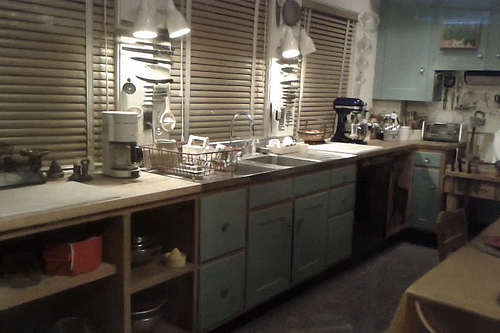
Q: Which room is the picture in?
A: It is at the kitchen.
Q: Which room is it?
A: It is a kitchen.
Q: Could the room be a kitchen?
A: Yes, it is a kitchen.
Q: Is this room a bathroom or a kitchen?
A: It is a kitchen.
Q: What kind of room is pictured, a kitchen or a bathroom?
A: It is a kitchen.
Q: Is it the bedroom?
A: No, it is the kitchen.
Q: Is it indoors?
A: Yes, it is indoors.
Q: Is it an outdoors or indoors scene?
A: It is indoors.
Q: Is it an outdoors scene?
A: No, it is indoors.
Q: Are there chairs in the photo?
A: Yes, there is a chair.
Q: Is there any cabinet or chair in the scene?
A: Yes, there is a chair.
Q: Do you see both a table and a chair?
A: Yes, there are both a chair and a table.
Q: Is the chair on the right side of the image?
A: Yes, the chair is on the right of the image.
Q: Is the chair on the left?
A: No, the chair is on the right of the image.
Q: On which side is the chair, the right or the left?
A: The chair is on the right of the image.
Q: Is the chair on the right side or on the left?
A: The chair is on the right of the image.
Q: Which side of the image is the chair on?
A: The chair is on the right of the image.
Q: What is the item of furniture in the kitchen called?
A: The piece of furniture is a chair.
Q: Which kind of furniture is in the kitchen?
A: The piece of furniture is a chair.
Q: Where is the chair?
A: The chair is in the kitchen.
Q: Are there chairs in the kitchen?
A: Yes, there is a chair in the kitchen.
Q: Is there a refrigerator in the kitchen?
A: No, there is a chair in the kitchen.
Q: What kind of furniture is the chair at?
A: The chair is at the table.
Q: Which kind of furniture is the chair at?
A: The chair is at the table.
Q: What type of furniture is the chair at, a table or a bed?
A: The chair is at a table.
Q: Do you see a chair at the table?
A: Yes, there is a chair at the table.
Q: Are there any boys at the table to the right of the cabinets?
A: No, there is a chair at the table.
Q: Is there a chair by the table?
A: Yes, there is a chair by the table.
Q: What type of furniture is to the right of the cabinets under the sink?
A: The piece of furniture is a chair.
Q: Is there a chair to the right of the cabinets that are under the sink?
A: Yes, there is a chair to the right of the cabinets.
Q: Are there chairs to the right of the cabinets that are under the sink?
A: Yes, there is a chair to the right of the cabinets.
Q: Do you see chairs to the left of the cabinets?
A: No, the chair is to the right of the cabinets.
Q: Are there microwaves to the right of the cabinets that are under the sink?
A: No, there is a chair to the right of the cabinets.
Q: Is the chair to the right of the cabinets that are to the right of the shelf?
A: Yes, the chair is to the right of the cabinets.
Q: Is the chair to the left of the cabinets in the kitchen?
A: No, the chair is to the right of the cabinets.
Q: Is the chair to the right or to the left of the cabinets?
A: The chair is to the right of the cabinets.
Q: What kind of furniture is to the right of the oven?
A: The piece of furniture is a chair.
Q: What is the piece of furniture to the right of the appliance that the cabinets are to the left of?
A: The piece of furniture is a chair.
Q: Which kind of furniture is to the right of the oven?
A: The piece of furniture is a chair.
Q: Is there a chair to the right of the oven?
A: Yes, there is a chair to the right of the oven.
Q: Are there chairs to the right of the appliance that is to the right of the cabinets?
A: Yes, there is a chair to the right of the oven.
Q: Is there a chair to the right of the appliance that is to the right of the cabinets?
A: Yes, there is a chair to the right of the oven.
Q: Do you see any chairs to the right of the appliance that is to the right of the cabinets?
A: Yes, there is a chair to the right of the oven.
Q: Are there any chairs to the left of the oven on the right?
A: No, the chair is to the right of the oven.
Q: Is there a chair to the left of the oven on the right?
A: No, the chair is to the right of the oven.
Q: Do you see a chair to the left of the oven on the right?
A: No, the chair is to the right of the oven.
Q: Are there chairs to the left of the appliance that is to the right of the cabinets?
A: No, the chair is to the right of the oven.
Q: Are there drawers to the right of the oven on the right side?
A: No, there is a chair to the right of the oven.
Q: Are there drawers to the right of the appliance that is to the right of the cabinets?
A: No, there is a chair to the right of the oven.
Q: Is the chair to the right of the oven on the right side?
A: Yes, the chair is to the right of the oven.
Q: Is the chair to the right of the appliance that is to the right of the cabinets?
A: Yes, the chair is to the right of the oven.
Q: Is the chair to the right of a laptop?
A: No, the chair is to the right of the oven.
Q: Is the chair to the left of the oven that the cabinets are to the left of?
A: No, the chair is to the right of the oven.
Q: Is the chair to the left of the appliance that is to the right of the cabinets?
A: No, the chair is to the right of the oven.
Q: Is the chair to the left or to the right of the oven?
A: The chair is to the right of the oven.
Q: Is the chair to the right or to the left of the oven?
A: The chair is to the right of the oven.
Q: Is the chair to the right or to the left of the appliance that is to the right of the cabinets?
A: The chair is to the right of the oven.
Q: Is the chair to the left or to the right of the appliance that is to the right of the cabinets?
A: The chair is to the right of the oven.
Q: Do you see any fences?
A: No, there are no fences.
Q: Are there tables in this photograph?
A: Yes, there is a table.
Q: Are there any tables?
A: Yes, there is a table.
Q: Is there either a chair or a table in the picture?
A: Yes, there is a table.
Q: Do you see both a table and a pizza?
A: No, there is a table but no pizzas.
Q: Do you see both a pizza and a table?
A: No, there is a table but no pizzas.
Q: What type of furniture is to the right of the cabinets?
A: The piece of furniture is a table.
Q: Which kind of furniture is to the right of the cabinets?
A: The piece of furniture is a table.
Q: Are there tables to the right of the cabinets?
A: Yes, there is a table to the right of the cabinets.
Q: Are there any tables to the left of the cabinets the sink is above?
A: No, the table is to the right of the cabinets.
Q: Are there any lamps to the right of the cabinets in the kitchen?
A: No, there is a table to the right of the cabinets.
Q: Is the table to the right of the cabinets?
A: Yes, the table is to the right of the cabinets.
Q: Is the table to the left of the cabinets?
A: No, the table is to the right of the cabinets.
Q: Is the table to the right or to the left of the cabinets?
A: The table is to the right of the cabinets.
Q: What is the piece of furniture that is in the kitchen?
A: The piece of furniture is a table.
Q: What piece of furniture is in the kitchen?
A: The piece of furniture is a table.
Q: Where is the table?
A: The table is in the kitchen.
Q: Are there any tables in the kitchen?
A: Yes, there is a table in the kitchen.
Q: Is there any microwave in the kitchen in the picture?
A: No, there is a table in the kitchen.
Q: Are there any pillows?
A: No, there are no pillows.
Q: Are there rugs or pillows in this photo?
A: No, there are no pillows or rugs.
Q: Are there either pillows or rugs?
A: No, there are no pillows or rugs.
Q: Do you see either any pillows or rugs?
A: No, there are no pillows or rugs.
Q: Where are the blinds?
A: The blinds are in the kitchen.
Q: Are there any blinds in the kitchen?
A: Yes, there are blinds in the kitchen.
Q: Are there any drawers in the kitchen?
A: No, there are blinds in the kitchen.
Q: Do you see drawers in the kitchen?
A: No, there are blinds in the kitchen.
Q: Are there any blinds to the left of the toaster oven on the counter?
A: Yes, there are blinds to the left of the toaster oven.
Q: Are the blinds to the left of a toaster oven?
A: Yes, the blinds are to the left of a toaster oven.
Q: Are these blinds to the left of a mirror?
A: No, the blinds are to the left of a toaster oven.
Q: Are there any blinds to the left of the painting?
A: Yes, there are blinds to the left of the painting.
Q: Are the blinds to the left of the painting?
A: Yes, the blinds are to the left of the painting.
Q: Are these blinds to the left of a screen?
A: No, the blinds are to the left of the painting.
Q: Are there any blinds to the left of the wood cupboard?
A: Yes, there are blinds to the left of the cupboard.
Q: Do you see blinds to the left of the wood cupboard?
A: Yes, there are blinds to the left of the cupboard.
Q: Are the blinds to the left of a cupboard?
A: Yes, the blinds are to the left of a cupboard.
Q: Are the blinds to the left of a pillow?
A: No, the blinds are to the left of a cupboard.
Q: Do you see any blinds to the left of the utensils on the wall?
A: Yes, there are blinds to the left of the utensils.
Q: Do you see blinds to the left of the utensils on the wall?
A: Yes, there are blinds to the left of the utensils.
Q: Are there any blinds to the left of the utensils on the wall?
A: Yes, there are blinds to the left of the utensils.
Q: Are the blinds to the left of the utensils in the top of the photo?
A: Yes, the blinds are to the left of the utensils.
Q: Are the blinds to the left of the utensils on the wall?
A: Yes, the blinds are to the left of the utensils.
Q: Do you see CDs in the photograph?
A: No, there are no cds.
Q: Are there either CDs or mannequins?
A: No, there are no CDs or mannequins.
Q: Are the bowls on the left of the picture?
A: Yes, the bowls are on the left of the image.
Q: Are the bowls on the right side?
A: No, the bowls are on the left of the image.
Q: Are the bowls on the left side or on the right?
A: The bowls are on the left of the image.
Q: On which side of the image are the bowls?
A: The bowls are on the left of the image.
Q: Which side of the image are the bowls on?
A: The bowls are on the left of the image.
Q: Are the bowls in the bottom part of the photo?
A: Yes, the bowls are in the bottom of the image.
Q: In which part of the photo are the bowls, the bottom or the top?
A: The bowls are in the bottom of the image.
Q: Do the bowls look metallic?
A: Yes, the bowls are metallic.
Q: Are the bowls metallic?
A: Yes, the bowls are metallic.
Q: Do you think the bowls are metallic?
A: Yes, the bowls are metallic.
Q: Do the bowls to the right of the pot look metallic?
A: Yes, the bowls are metallic.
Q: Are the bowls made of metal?
A: Yes, the bowls are made of metal.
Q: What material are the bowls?
A: The bowls are made of metal.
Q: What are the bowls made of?
A: The bowls are made of metal.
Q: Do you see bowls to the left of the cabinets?
A: Yes, there are bowls to the left of the cabinets.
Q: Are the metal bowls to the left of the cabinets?
A: Yes, the bowls are to the left of the cabinets.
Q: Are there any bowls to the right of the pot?
A: Yes, there are bowls to the right of the pot.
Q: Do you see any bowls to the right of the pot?
A: Yes, there are bowls to the right of the pot.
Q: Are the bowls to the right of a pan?
A: No, the bowls are to the right of the pot.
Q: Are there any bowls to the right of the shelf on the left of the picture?
A: Yes, there are bowls to the right of the shelf.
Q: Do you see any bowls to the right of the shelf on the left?
A: Yes, there are bowls to the right of the shelf.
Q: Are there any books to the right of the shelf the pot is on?
A: No, there are bowls to the right of the shelf.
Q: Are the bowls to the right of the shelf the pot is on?
A: Yes, the bowls are to the right of the shelf.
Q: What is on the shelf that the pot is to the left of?
A: The bowls are on the shelf.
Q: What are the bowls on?
A: The bowls are on the shelf.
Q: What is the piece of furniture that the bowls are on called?
A: The piece of furniture is a shelf.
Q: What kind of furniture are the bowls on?
A: The bowls are on the shelf.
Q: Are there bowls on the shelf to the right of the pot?
A: Yes, there are bowls on the shelf.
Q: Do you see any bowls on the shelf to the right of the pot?
A: Yes, there are bowls on the shelf.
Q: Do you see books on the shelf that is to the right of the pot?
A: No, there are bowls on the shelf.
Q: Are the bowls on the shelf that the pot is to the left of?
A: Yes, the bowls are on the shelf.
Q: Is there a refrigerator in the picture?
A: No, there are no refrigerators.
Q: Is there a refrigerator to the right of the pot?
A: No, there is a shelf to the right of the pot.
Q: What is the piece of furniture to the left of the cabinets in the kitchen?
A: The piece of furniture is a shelf.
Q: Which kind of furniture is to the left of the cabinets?
A: The piece of furniture is a shelf.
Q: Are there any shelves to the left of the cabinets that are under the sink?
A: Yes, there is a shelf to the left of the cabinets.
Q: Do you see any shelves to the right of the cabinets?
A: No, the shelf is to the left of the cabinets.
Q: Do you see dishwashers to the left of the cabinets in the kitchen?
A: No, there is a shelf to the left of the cabinets.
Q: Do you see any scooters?
A: No, there are no scooters.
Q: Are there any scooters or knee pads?
A: No, there are no scooters or knee pads.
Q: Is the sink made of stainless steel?
A: Yes, the sink is made of stainless steel.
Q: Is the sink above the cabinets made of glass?
A: No, the sink is made of stainless steel.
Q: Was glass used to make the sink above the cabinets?
A: No, the sink is made of stainless steel.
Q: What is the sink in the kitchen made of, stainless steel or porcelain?
A: The sink is made of stainless steel.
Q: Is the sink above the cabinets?
A: Yes, the sink is above the cabinets.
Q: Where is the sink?
A: The sink is in the kitchen.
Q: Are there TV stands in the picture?
A: No, there are no TV stands.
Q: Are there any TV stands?
A: No, there are no TV stands.